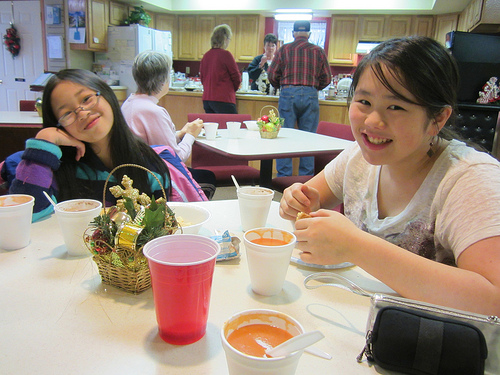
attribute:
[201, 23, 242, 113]
person — here, lady, standing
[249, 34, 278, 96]
person — here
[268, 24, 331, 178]
person — here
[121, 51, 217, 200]
person — here, sitting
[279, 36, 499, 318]
person — here, young, asian, smiling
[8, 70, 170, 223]
person — here, asian, smiling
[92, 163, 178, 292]
basket — centerpiece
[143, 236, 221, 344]
cup — here, red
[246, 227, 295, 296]
cup — here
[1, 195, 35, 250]
cup — here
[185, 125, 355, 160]
table — here, white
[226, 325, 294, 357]
liquid — orange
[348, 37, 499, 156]
hair — dark, pulled back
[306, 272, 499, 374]
bag — here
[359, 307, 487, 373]
bag — black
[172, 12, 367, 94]
wall — here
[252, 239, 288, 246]
liquid — orange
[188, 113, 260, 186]
chair — empty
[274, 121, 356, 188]
chair — empty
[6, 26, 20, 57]
decor — seasonal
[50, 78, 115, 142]
head — tilted